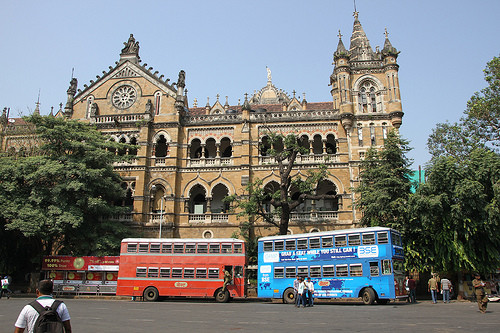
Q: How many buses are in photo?
A: Two.